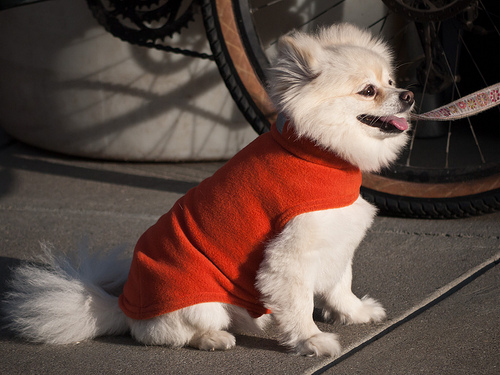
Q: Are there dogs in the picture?
A: Yes, there is a dog.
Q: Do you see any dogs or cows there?
A: Yes, there is a dog.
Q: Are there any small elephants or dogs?
A: Yes, there is a small dog.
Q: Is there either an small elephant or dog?
A: Yes, there is a small dog.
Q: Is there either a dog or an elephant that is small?
A: Yes, the dog is small.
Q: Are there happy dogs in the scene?
A: Yes, there is a happy dog.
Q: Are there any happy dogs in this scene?
A: Yes, there is a happy dog.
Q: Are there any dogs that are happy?
A: Yes, there is a dog that is happy.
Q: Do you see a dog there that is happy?
A: Yes, there is a dog that is happy.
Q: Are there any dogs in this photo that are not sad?
A: Yes, there is a happy dog.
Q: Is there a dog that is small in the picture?
A: Yes, there is a small dog.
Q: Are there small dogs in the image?
A: Yes, there is a small dog.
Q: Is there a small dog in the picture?
A: Yes, there is a small dog.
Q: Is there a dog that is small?
A: Yes, there is a dog that is small.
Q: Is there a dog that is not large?
A: Yes, there is a small dog.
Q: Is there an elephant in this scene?
A: No, there are no elephants.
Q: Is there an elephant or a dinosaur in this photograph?
A: No, there are no elephants or dinosaurs.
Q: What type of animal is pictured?
A: The animal is a dog.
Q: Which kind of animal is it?
A: The animal is a dog.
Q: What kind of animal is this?
A: That is a dog.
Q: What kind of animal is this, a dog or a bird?
A: That is a dog.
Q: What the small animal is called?
A: The animal is a dog.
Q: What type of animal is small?
A: The animal is a dog.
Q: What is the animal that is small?
A: The animal is a dog.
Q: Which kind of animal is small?
A: The animal is a dog.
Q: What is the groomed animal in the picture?
A: The animal is a dog.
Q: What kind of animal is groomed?
A: The animal is a dog.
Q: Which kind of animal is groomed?
A: The animal is a dog.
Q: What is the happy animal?
A: The animal is a dog.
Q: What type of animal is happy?
A: The animal is a dog.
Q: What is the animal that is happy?
A: The animal is a dog.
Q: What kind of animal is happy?
A: The animal is a dog.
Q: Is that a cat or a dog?
A: That is a dog.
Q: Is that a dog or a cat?
A: That is a dog.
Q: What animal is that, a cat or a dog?
A: That is a dog.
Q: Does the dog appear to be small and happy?
A: Yes, the dog is small and happy.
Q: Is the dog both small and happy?
A: Yes, the dog is small and happy.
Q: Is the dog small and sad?
A: No, the dog is small but happy.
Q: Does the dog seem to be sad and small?
A: No, the dog is small but happy.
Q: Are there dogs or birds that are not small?
A: No, there is a dog but it is small.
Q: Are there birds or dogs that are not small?
A: No, there is a dog but it is small.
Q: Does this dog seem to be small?
A: Yes, the dog is small.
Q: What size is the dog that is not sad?
A: The dog is small.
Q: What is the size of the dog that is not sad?
A: The dog is small.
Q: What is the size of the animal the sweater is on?
A: The dog is small.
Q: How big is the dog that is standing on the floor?
A: The dog is small.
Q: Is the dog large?
A: No, the dog is small.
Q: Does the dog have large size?
A: No, the dog is small.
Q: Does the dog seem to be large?
A: No, the dog is small.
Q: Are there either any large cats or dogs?
A: No, there is a dog but it is small.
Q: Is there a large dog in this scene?
A: No, there is a dog but it is small.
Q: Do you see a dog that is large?
A: No, there is a dog but it is small.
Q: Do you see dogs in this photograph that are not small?
A: No, there is a dog but it is small.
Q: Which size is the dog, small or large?
A: The dog is small.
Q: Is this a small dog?
A: Yes, this is a small dog.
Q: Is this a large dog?
A: No, this is a small dog.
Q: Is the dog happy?
A: Yes, the dog is happy.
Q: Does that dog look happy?
A: Yes, the dog is happy.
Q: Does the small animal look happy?
A: Yes, the dog is happy.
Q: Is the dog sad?
A: No, the dog is happy.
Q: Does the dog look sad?
A: No, the dog is happy.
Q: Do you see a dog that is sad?
A: No, there is a dog but it is happy.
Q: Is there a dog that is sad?
A: No, there is a dog but it is happy.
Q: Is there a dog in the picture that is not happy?
A: No, there is a dog but it is happy.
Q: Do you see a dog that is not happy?
A: No, there is a dog but it is happy.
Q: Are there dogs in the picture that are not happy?
A: No, there is a dog but it is happy.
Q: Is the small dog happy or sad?
A: The dog is happy.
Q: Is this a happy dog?
A: Yes, this is a happy dog.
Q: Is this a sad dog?
A: No, this is a happy dog.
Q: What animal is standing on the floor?
A: The dog is standing on the floor.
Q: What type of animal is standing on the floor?
A: The animal is a dog.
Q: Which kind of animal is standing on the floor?
A: The animal is a dog.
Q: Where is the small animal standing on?
A: The dog is standing on the floor.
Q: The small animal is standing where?
A: The dog is standing on the floor.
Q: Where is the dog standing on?
A: The dog is standing on the floor.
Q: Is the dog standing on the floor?
A: Yes, the dog is standing on the floor.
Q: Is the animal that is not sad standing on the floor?
A: Yes, the dog is standing on the floor.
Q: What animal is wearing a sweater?
A: The animal is a dog.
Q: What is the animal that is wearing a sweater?
A: The animal is a dog.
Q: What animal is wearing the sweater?
A: The animal is a dog.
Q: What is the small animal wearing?
A: The dog is wearing a sweater.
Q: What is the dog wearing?
A: The dog is wearing a sweater.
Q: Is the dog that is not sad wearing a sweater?
A: Yes, the dog is wearing a sweater.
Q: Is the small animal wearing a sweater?
A: Yes, the dog is wearing a sweater.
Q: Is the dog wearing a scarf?
A: No, the dog is wearing a sweater.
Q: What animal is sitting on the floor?
A: The animal is a dog.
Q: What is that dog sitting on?
A: The dog is sitting on the floor.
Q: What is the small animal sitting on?
A: The dog is sitting on the floor.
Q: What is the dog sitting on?
A: The dog is sitting on the floor.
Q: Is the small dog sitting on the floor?
A: Yes, the dog is sitting on the floor.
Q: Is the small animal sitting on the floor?
A: Yes, the dog is sitting on the floor.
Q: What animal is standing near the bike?
A: The dog is standing near the bike.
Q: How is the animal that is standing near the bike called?
A: The animal is a dog.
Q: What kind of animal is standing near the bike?
A: The animal is a dog.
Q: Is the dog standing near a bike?
A: Yes, the dog is standing near a bike.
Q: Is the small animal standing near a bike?
A: Yes, the dog is standing near a bike.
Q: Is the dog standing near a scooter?
A: No, the dog is standing near a bike.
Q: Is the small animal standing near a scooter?
A: No, the dog is standing near a bike.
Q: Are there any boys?
A: No, there are no boys.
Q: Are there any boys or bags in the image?
A: No, there are no boys or bags.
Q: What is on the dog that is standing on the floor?
A: The sweater is on the dog.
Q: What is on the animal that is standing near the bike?
A: The sweater is on the dog.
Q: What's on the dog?
A: The sweater is on the dog.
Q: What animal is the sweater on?
A: The sweater is on the dog.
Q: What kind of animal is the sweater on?
A: The sweater is on the dog.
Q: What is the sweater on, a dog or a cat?
A: The sweater is on a dog.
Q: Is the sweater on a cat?
A: No, the sweater is on the dog.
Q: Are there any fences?
A: No, there are no fences.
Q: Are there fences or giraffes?
A: No, there are no fences or giraffes.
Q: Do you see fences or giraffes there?
A: No, there are no fences or giraffes.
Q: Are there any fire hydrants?
A: No, there are no fire hydrants.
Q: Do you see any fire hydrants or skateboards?
A: No, there are no fire hydrants or skateboards.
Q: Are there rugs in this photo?
A: No, there are no rugs.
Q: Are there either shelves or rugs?
A: No, there are no rugs or shelves.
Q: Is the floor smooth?
A: Yes, the floor is smooth.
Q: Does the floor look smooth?
A: Yes, the floor is smooth.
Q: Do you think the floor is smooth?
A: Yes, the floor is smooth.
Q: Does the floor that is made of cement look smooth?
A: Yes, the floor is smooth.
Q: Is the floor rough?
A: No, the floor is smooth.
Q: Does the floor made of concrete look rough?
A: No, the floor is smooth.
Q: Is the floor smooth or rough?
A: The floor is smooth.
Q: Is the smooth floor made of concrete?
A: Yes, the floor is made of concrete.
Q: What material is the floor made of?
A: The floor is made of concrete.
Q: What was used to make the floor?
A: The floor is made of concrete.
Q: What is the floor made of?
A: The floor is made of concrete.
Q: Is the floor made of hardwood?
A: No, the floor is made of cement.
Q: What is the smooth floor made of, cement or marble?
A: The floor is made of cement.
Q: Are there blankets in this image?
A: No, there are no blankets.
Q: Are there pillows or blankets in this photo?
A: No, there are no blankets or pillows.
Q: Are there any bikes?
A: Yes, there is a bike.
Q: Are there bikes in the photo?
A: Yes, there is a bike.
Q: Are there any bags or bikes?
A: Yes, there is a bike.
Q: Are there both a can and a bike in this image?
A: No, there is a bike but no cans.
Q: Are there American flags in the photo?
A: No, there are no American flags.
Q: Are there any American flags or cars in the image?
A: No, there are no American flags or cars.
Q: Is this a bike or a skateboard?
A: This is a bike.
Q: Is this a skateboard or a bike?
A: This is a bike.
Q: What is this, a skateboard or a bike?
A: This is a bike.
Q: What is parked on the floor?
A: The bike is parked on the floor.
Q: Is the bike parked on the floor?
A: Yes, the bike is parked on the floor.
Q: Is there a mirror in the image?
A: No, there are no mirrors.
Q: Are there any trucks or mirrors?
A: No, there are no mirrors or trucks.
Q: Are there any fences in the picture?
A: No, there are no fences.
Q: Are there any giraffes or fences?
A: No, there are no fences or giraffes.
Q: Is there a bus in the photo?
A: No, there are no buses.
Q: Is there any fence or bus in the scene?
A: No, there are no buses or fences.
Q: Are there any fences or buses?
A: No, there are no buses or fences.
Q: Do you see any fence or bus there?
A: No, there are no buses or fences.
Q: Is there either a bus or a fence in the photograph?
A: No, there are no buses or fences.